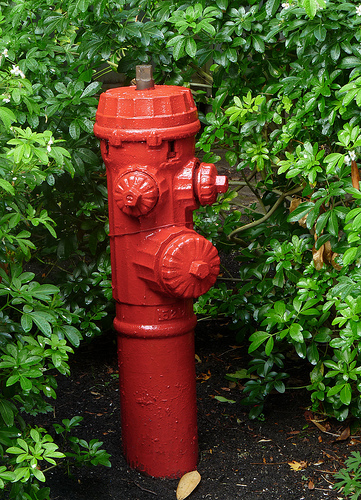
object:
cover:
[114, 171, 158, 217]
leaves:
[0, 259, 84, 401]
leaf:
[177, 469, 201, 499]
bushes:
[0, 0, 360, 500]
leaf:
[276, 262, 283, 273]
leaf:
[209, 285, 245, 320]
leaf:
[265, 337, 274, 357]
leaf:
[248, 335, 270, 354]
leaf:
[249, 331, 268, 341]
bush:
[290, 0, 361, 500]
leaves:
[164, 0, 216, 56]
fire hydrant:
[93, 64, 229, 477]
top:
[93, 64, 198, 129]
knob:
[215, 175, 228, 194]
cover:
[158, 234, 219, 298]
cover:
[94, 84, 201, 136]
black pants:
[94, 64, 228, 478]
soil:
[215, 428, 306, 486]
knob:
[136, 65, 155, 90]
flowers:
[9, 64, 25, 79]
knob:
[189, 260, 210, 279]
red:
[92, 85, 227, 481]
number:
[157, 308, 187, 321]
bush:
[121, 0, 221, 86]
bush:
[1, 0, 93, 500]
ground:
[0, 349, 361, 500]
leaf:
[266, 236, 291, 276]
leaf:
[301, 279, 324, 326]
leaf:
[29, 312, 54, 336]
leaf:
[21, 369, 43, 378]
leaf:
[286, 169, 303, 179]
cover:
[198, 162, 229, 207]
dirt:
[200, 429, 285, 499]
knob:
[122, 188, 141, 207]